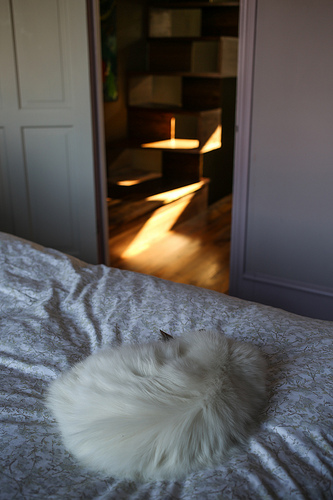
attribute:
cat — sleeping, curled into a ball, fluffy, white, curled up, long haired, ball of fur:
[45, 328, 273, 485]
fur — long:
[46, 330, 272, 488]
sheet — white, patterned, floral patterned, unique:
[1, 232, 332, 499]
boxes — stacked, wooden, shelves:
[107, 1, 239, 206]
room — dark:
[100, 1, 240, 294]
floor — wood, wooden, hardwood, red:
[108, 194, 232, 299]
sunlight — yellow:
[127, 225, 228, 289]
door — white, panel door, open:
[0, 1, 102, 264]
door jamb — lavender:
[231, 0, 255, 297]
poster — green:
[102, 3, 117, 102]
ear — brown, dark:
[160, 330, 173, 342]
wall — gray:
[229, 0, 332, 321]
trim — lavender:
[230, 275, 332, 324]